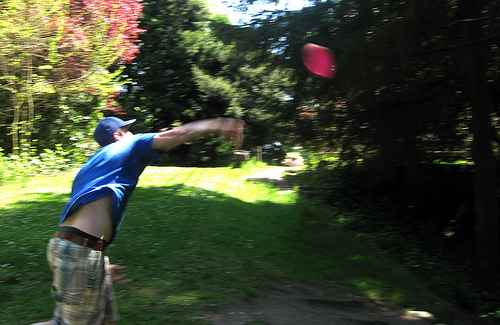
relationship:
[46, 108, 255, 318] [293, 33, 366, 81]
man tossing football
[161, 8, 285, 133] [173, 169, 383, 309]
trees in field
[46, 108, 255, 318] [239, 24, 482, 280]
man in forest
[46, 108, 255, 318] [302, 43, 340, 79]
man throwing football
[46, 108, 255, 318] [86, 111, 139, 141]
man wearing cap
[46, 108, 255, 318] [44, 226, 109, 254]
man wearing a belt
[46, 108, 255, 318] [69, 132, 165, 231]
man wearing shirt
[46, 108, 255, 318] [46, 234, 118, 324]
man wearing pants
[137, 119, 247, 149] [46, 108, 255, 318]
arm of man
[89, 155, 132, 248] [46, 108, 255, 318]
side of man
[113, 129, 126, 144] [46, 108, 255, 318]
ear of man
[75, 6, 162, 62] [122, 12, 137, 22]
tree has bright flower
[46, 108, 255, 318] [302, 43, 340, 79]
man throws football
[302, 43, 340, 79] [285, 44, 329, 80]
football in motion